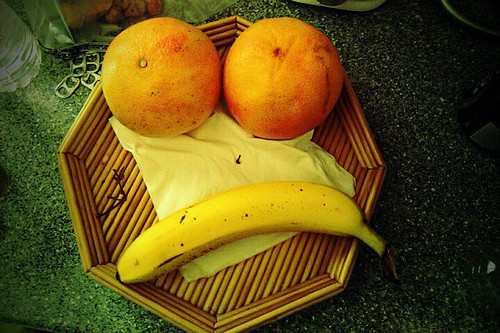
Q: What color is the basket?
A: Brown.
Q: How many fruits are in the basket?
A: Three.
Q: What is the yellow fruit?
A: A banana.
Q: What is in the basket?
A: Fruit and a napkin.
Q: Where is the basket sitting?
A: On the counter.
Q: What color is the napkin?
A: White.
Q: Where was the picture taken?
A: The kitchen.